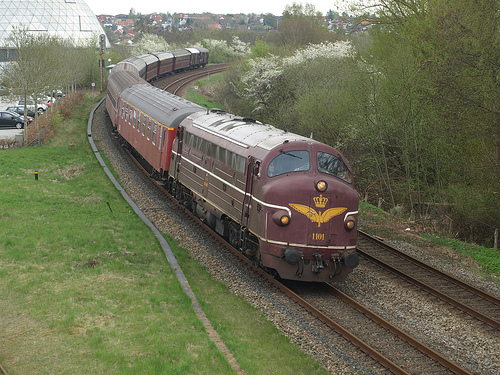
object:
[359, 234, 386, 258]
tracks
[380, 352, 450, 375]
tracks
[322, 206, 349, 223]
wings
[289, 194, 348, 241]
crown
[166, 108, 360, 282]
car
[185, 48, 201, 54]
roof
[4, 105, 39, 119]
cars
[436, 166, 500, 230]
trees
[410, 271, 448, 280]
tracks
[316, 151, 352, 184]
window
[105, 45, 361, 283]
train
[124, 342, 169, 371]
grass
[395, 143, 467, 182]
trees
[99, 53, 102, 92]
post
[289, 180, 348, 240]
sign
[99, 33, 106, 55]
light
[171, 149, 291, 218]
line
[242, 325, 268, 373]
grass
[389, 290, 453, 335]
stone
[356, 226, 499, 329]
railways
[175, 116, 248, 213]
steel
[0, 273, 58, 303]
grass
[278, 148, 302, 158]
wiper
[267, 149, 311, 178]
glass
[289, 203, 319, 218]
tip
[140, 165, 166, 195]
tracks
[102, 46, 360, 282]
locomotive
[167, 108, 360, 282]
engine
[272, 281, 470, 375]
rails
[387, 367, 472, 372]
track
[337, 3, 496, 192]
foliage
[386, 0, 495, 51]
trees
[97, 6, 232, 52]
houses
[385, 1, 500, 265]
hillside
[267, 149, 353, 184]
windshield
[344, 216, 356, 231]
headlight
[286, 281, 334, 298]
track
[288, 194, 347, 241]
symbol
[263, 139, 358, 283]
front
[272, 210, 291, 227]
light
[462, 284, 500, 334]
track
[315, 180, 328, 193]
light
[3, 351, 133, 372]
grass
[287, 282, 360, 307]
track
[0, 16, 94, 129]
trees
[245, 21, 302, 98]
trees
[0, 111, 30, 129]
cars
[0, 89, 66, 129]
lot